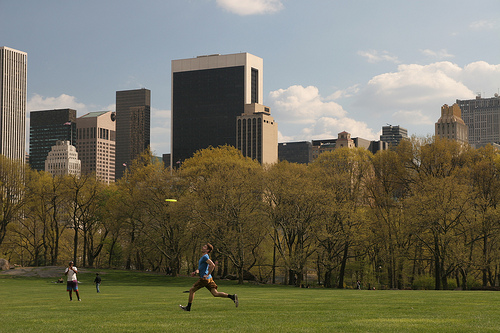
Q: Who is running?
A: The young man.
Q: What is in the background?
A: The city.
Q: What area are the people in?
A: Large wooded area.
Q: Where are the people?
A: Park in the city.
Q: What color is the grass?
A: Green.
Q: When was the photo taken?
A: Afternoon.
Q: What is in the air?
A: Frisbee.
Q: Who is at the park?
A: A few people.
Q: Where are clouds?
A: In the sky.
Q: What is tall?
A: Buildings.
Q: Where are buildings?
A: In the distance.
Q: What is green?
A: Grass.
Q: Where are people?
A: In a park.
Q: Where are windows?
A: On buildings.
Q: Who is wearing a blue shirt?
A: Man running.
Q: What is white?
A: Clouds.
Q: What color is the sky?
A: Blue.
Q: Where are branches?
A: On trees.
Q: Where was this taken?
A: Park.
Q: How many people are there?
A: 3.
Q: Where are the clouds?
A: In the sky.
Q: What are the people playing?
A: Frisbee.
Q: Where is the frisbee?
A: In the air.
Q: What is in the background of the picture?
A: Buildings.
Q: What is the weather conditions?
A: Partially Cloudy.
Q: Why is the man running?
A: To catch the frisbee.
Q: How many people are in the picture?
A: 3.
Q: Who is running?
A: The man in the blue shirt.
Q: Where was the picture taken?
A: A park.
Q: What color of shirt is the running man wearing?
A: Blue.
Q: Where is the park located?
A: In the city.